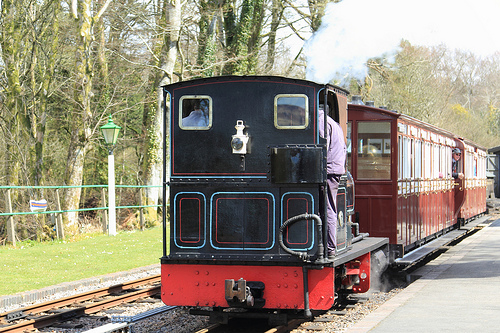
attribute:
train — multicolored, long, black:
[131, 68, 500, 317]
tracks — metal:
[10, 294, 160, 332]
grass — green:
[7, 241, 138, 277]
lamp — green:
[91, 105, 138, 238]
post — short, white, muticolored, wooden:
[95, 111, 123, 239]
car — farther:
[449, 126, 493, 241]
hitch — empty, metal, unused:
[215, 264, 257, 314]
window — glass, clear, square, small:
[175, 88, 214, 138]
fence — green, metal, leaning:
[9, 178, 94, 245]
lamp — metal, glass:
[93, 108, 132, 155]